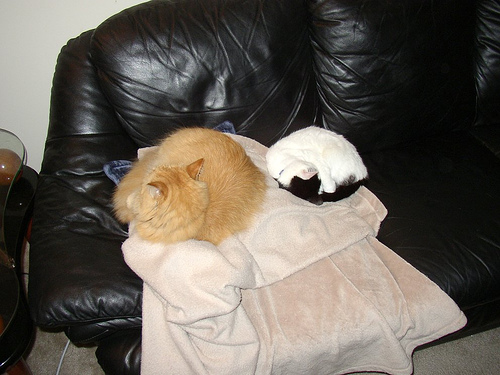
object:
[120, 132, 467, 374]
blanket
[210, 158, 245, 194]
tan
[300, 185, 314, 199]
black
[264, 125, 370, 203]
cat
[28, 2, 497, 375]
couch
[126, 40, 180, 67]
black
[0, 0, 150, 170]
wall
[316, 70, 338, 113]
wrinkles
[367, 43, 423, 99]
leather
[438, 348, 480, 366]
gray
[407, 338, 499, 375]
floor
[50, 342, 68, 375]
cord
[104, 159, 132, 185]
jeans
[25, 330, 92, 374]
carpet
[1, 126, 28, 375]
guitar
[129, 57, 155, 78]
light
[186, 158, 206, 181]
ear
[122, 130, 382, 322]
pillow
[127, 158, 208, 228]
head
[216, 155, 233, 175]
fur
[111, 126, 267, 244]
cat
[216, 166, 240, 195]
orange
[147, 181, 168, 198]
ears